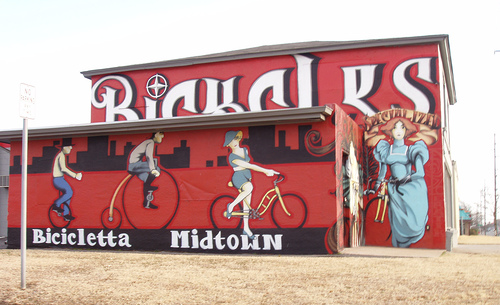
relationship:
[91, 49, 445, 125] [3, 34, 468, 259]
word on house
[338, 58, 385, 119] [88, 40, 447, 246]
letter on side of wall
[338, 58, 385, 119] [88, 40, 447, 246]
letter on wall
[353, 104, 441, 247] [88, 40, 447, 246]
picture on wall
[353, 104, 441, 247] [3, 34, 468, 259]
picture on side of house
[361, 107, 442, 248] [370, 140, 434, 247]
woman in a dress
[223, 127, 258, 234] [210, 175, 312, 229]
woman standing on a bike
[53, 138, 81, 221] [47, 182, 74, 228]
man on a unicycle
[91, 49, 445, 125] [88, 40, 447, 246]
word on wall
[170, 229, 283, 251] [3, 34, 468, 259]
word on house